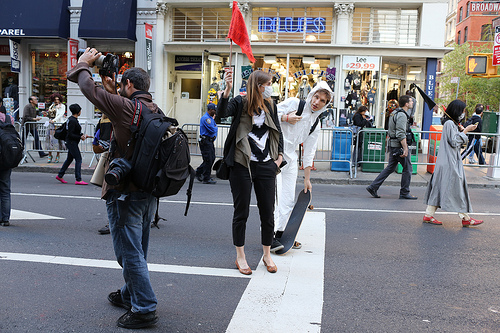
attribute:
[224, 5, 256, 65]
flag — red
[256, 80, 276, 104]
mask — white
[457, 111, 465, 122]
mask — white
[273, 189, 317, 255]
skateboard — black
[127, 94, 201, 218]
backpack — black, slightly open, large, man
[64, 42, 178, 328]
man — photographing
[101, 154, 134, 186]
camera — black, hanging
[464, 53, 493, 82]
signal — crosswalk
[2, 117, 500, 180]
fence — metal, long, gray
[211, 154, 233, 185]
pocketbook — black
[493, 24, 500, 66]
signs — red, white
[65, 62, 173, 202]
shirt — brown, long sleeve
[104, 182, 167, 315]
jeans — blue, denim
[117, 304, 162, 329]
shoes — black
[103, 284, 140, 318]
shoes — black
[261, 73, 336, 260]
people — in white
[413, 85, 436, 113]
flag — black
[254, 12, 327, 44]
sign — blue neon, hanging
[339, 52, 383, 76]
sign — advertising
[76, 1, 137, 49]
awning — black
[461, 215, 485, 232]
shoes — red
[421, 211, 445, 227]
shoes — red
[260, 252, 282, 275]
shoes — brown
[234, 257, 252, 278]
shoes — brown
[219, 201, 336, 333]
line — thick, white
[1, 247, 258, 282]
line — thick, white, long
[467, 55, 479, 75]
hand — red, signal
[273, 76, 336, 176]
shirt — white, hooded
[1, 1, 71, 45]
awning — blue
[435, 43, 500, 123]
tree — large, green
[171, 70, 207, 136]
door — white